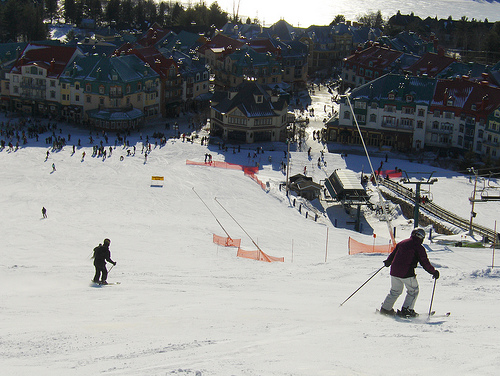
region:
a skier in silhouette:
[87, 234, 119, 292]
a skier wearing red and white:
[337, 222, 459, 332]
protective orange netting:
[210, 232, 242, 250]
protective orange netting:
[231, 241, 289, 266]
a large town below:
[3, 12, 498, 152]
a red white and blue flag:
[145, 172, 166, 189]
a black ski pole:
[337, 257, 392, 309]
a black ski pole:
[425, 273, 439, 317]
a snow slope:
[10, 141, 491, 371]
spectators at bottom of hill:
[2, 119, 162, 157]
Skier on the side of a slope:
[336, 224, 467, 336]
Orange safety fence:
[205, 230, 291, 268]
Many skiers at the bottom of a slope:
[0, 124, 168, 171]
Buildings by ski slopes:
[22, 16, 484, 166]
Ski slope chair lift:
[291, 160, 406, 227]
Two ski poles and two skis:
[328, 251, 460, 333]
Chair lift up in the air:
[462, 169, 498, 204]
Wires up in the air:
[330, 71, 397, 210]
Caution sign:
[132, 170, 174, 194]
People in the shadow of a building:
[0, 119, 135, 171]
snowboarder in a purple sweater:
[376, 227, 438, 318]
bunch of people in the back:
[3, 107, 276, 171]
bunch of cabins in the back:
[0, 0, 494, 147]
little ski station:
[283, 168, 371, 207]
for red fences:
[211, 234, 399, 264]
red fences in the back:
[187, 157, 269, 175]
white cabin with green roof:
[339, 74, 431, 149]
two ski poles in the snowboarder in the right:
[339, 260, 439, 312]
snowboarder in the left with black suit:
[87, 236, 122, 286]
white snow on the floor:
[5, 111, 497, 373]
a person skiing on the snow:
[299, 170, 499, 320]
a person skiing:
[357, 198, 493, 343]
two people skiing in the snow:
[51, 191, 472, 344]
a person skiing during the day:
[316, 184, 494, 359]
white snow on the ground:
[127, 227, 342, 373]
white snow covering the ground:
[130, 223, 274, 373]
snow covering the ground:
[168, 273, 268, 371]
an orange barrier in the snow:
[187, 193, 312, 293]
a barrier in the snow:
[185, 203, 308, 298]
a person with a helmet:
[318, 206, 480, 339]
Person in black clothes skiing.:
[87, 234, 119, 286]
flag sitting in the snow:
[152, 174, 168, 189]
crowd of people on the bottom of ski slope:
[1, 123, 168, 170]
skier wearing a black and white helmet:
[338, 226, 447, 331]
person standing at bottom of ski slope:
[39, 204, 51, 224]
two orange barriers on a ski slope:
[185, 181, 292, 266]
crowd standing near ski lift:
[302, 146, 328, 178]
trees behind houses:
[2, 1, 235, 25]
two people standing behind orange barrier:
[202, 152, 213, 164]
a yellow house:
[57, 78, 74, 108]